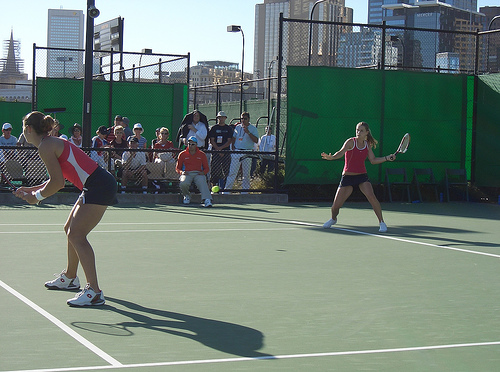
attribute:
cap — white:
[2, 120, 14, 135]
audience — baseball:
[2, 105, 282, 211]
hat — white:
[131, 121, 144, 131]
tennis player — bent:
[8, 110, 118, 305]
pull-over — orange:
[174, 148, 211, 178]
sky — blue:
[0, 0, 500, 81]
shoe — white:
[378, 218, 390, 235]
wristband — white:
[19, 186, 59, 207]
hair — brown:
[23, 109, 55, 136]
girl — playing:
[318, 117, 405, 231]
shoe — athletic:
[377, 218, 389, 235]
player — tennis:
[12, 105, 149, 345]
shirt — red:
[175, 147, 205, 174]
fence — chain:
[276, 6, 489, 78]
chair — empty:
[442, 163, 473, 203]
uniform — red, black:
[335, 137, 374, 187]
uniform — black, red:
[50, 134, 118, 214]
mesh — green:
[300, 73, 464, 187]